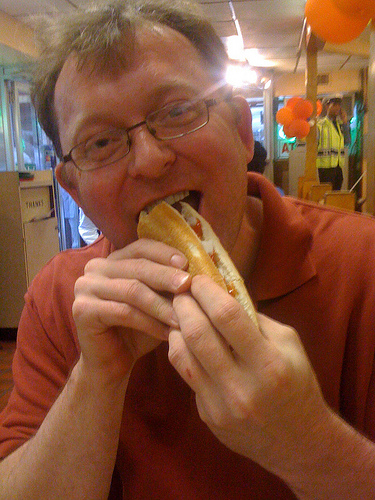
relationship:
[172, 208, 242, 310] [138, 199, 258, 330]
hot dog in  a bun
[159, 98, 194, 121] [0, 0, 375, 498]
eye of a man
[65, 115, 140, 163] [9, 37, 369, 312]
eye of a man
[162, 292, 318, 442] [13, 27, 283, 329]
hand of a man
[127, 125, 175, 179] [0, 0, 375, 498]
nose of a man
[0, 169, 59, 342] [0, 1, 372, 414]
trash can inside a restaurant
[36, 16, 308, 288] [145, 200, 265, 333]
man holding hot dog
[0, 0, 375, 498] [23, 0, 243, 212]
man with hair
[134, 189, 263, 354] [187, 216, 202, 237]
hot dog with ketchup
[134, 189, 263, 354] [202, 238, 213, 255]
hot dog with onion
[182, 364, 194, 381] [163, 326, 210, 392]
cut on finger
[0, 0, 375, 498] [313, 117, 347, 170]
man in vest